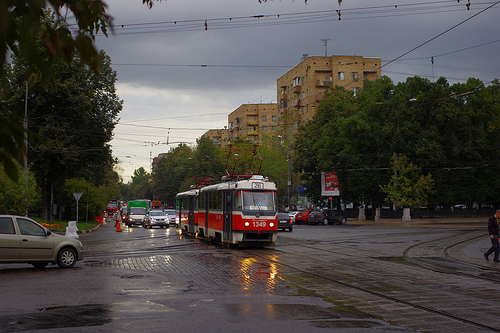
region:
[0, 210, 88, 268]
a stopped car on the street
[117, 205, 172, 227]
motor vehicles behind the electric train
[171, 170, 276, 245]
a red and white train moving on the street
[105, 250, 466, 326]
rain on the street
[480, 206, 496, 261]
a man walking beside the street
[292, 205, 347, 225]
automobiles parked in front of the curb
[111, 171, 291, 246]
traffic moving on the wet street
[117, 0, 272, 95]
dark clouds in the sky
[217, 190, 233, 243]
a door on the side of the electric train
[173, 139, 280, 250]
a transit electric train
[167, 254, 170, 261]
Car reflecting light on the road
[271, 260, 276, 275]
Reflection of front light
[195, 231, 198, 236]
Light shining under the bus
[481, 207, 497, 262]
Person walking on the road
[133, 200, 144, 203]
Green color on vehicle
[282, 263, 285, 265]
Bus track in the center of the road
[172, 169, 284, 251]
A red tram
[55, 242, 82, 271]
The right front tire of a car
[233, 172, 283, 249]
The front of a tram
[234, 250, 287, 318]
The reflection of headlights on a wet street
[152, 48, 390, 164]
A row of buildings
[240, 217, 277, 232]
The headlights of a tram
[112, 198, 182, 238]
The fronts of cars on a wet street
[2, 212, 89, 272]
The side of a car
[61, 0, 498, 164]
Overhead wires above a street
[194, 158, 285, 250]
Vehicle on the street.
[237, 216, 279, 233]
Headlights on the vehicle.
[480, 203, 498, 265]
Person walking on the street.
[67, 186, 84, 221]
Sign beside the street.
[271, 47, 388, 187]
Building in the background.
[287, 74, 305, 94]
balcony on the building.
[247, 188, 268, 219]
Wiper on the window.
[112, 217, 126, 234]
Orange cone on the street.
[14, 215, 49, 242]
window in the car.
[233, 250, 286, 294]
Reflection of headlights on pavement.